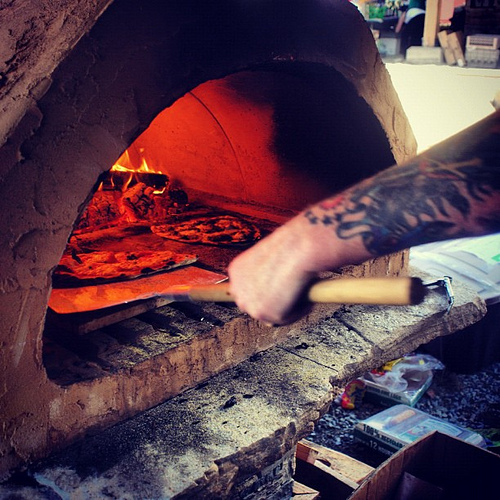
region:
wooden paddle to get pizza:
[76, 289, 447, 335]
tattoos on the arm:
[306, 149, 477, 232]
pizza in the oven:
[94, 210, 291, 277]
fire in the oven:
[97, 162, 214, 218]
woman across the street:
[386, 3, 447, 71]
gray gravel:
[451, 370, 497, 433]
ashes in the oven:
[93, 201, 196, 222]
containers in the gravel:
[367, 388, 498, 444]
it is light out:
[375, 9, 496, 106]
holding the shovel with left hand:
[225, 212, 394, 355]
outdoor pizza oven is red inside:
[25, 48, 416, 394]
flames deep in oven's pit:
[99, 146, 177, 201]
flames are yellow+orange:
[100, 143, 186, 198]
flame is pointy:
[138, 144, 153, 172]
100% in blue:
[358, 419, 383, 442]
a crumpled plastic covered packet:
[334, 344, 446, 414]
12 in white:
[366, 438, 378, 452]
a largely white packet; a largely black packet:
[341, 401, 487, 482]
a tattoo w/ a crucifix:
[355, 148, 485, 188]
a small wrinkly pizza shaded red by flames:
[144, 208, 264, 247]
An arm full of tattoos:
[311, 97, 491, 309]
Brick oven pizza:
[51, 188, 209, 325]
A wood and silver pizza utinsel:
[31, 224, 472, 394]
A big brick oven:
[1, 2, 498, 483]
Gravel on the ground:
[452, 363, 484, 425]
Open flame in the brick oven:
[66, 132, 192, 255]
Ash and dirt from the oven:
[16, 363, 356, 423]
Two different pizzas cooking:
[7, 137, 289, 344]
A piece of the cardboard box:
[324, 412, 498, 490]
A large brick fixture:
[0, 5, 395, 163]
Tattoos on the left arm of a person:
[300, 150, 477, 254]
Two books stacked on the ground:
[351, 393, 496, 458]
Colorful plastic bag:
[328, 375, 375, 411]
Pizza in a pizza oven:
[144, 209, 261, 250]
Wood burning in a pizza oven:
[62, 162, 183, 232]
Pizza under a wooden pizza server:
[42, 244, 210, 314]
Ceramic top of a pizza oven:
[0, 7, 411, 99]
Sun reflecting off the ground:
[400, 71, 478, 121]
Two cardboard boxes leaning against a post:
[433, 24, 468, 71]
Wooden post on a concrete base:
[416, 0, 448, 50]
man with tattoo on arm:
[201, 92, 493, 393]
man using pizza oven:
[10, 124, 390, 434]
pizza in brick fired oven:
[78, 168, 330, 373]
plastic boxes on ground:
[331, 312, 496, 496]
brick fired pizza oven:
[14, 27, 425, 411]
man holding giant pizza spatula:
[57, 184, 457, 394]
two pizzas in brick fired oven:
[18, 74, 356, 349]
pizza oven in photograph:
[21, 32, 419, 440]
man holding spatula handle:
[90, 230, 435, 392]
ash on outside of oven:
[61, 252, 482, 497]